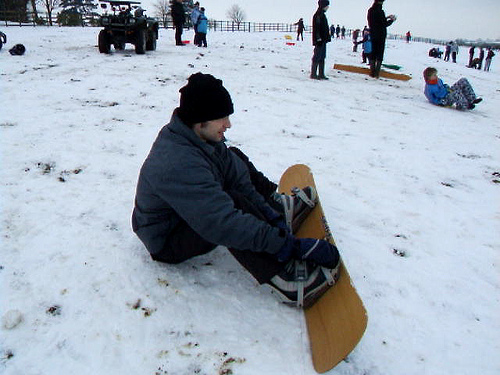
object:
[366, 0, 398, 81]
adult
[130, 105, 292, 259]
jacket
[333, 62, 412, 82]
object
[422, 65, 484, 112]
child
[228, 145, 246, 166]
knee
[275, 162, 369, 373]
snowboard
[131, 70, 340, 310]
man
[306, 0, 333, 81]
person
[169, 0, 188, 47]
person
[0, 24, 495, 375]
slope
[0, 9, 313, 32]
fencing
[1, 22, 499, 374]
hill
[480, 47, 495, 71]
people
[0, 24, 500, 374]
ground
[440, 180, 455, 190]
dark holes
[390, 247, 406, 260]
dark holes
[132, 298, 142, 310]
dark holes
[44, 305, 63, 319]
dark holes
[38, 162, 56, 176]
dark holes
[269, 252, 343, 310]
feet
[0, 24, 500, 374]
snow